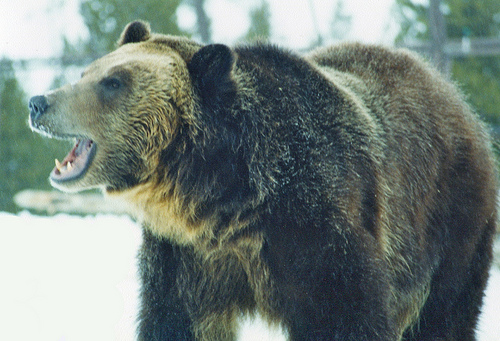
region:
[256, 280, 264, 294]
bottom of a bear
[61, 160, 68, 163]
part of a tooth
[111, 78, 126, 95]
eye of a bear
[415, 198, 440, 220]
back of a bear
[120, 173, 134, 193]
part of a mouth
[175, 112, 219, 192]
edge of a bear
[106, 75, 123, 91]
The bears eye is black.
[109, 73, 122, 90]
THe bears eye is small.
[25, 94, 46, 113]
The bears nose is black.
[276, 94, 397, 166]
The bears fur is brown.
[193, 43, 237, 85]
The bears ear is brown.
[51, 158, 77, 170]
The bears teeth are sharp.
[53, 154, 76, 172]
The bears teeth are yellow.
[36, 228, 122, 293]
The snow in the background is white.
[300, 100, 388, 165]
The bears fur is damp.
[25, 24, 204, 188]
The bears mouth is opened.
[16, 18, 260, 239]
A bear is roaring.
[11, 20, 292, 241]
A bear is opening its mouth.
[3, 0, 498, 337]
A bear in snow.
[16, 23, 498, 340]
A bear is standing.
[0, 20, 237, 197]
A bear is staring to the left.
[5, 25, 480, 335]
An adult bear standing up.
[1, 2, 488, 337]
A bear is in the forest.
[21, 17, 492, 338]
The bear is stepping on snow.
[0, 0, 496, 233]
The bear is behind some trees.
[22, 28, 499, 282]
A bear has snow in its fur.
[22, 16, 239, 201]
the head of a bear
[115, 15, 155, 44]
the ear of a bear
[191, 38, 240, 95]
the ear of a bear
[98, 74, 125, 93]
the eye of a bear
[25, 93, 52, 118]
the nose of a bear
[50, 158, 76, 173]
the teeth in a bear's mouth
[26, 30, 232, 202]
a bear with it's mouth open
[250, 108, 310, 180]
the fur of a bear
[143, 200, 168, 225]
the fur of a bear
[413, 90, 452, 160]
the fur of a bear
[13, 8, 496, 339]
a bear color brown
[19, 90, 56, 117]
nose of bear is black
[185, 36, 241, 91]
right ear of bear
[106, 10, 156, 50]
left ear of bear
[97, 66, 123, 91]
eye of bear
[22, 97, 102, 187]
mouth of bear is open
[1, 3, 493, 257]
green trees behind the bear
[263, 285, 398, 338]
right leg of bear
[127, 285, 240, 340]
left leg of bear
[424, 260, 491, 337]
back leg of bear